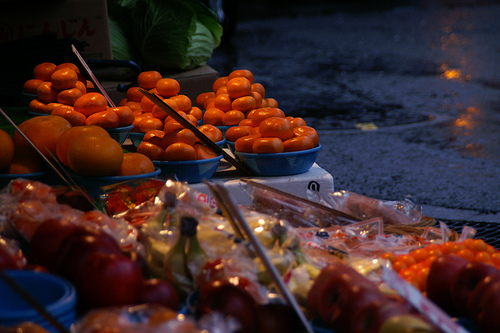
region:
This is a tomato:
[68, 123, 135, 188]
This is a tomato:
[115, 136, 156, 183]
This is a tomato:
[80, 85, 114, 110]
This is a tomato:
[118, 99, 166, 130]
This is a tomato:
[140, 58, 160, 93]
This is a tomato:
[152, 76, 187, 93]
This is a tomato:
[161, 128, 208, 170]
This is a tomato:
[187, 108, 224, 150]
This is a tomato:
[62, 82, 110, 116]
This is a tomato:
[217, 96, 267, 153]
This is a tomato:
[232, 119, 273, 157]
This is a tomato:
[284, 122, 321, 162]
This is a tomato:
[262, 109, 303, 137]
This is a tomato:
[221, 68, 268, 112]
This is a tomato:
[150, 105, 205, 145]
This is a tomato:
[38, 55, 73, 97]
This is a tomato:
[17, 106, 71, 151]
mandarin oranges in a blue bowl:
[222, 110, 328, 182]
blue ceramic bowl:
[227, 145, 322, 180]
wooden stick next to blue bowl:
[135, 92, 240, 168]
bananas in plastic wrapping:
[115, 187, 240, 284]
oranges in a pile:
[199, 72, 280, 135]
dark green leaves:
[109, 3, 236, 79]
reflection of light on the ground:
[427, 23, 498, 168]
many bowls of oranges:
[0, 58, 329, 190]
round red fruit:
[38, 214, 176, 322]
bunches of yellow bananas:
[142, 185, 329, 294]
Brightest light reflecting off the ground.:
[438, 66, 462, 78]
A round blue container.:
[1, 265, 76, 330]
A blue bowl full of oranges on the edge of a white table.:
[233, 139, 322, 173]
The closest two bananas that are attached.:
[160, 213, 212, 279]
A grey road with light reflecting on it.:
[239, 0, 498, 212]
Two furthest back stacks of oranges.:
[24, 57, 135, 129]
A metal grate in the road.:
[426, 213, 499, 248]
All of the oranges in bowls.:
[1, 58, 313, 173]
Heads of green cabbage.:
[108, 0, 224, 68]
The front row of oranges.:
[197, 68, 319, 153]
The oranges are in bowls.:
[25, 61, 297, 157]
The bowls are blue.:
[154, 149, 339, 174]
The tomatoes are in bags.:
[8, 187, 453, 324]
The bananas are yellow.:
[133, 188, 320, 288]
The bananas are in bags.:
[133, 193, 320, 290]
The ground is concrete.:
[243, 12, 498, 212]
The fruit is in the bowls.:
[16, 57, 491, 332]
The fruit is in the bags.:
[14, 162, 476, 328]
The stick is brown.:
[207, 174, 319, 330]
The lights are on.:
[436, 54, 483, 174]